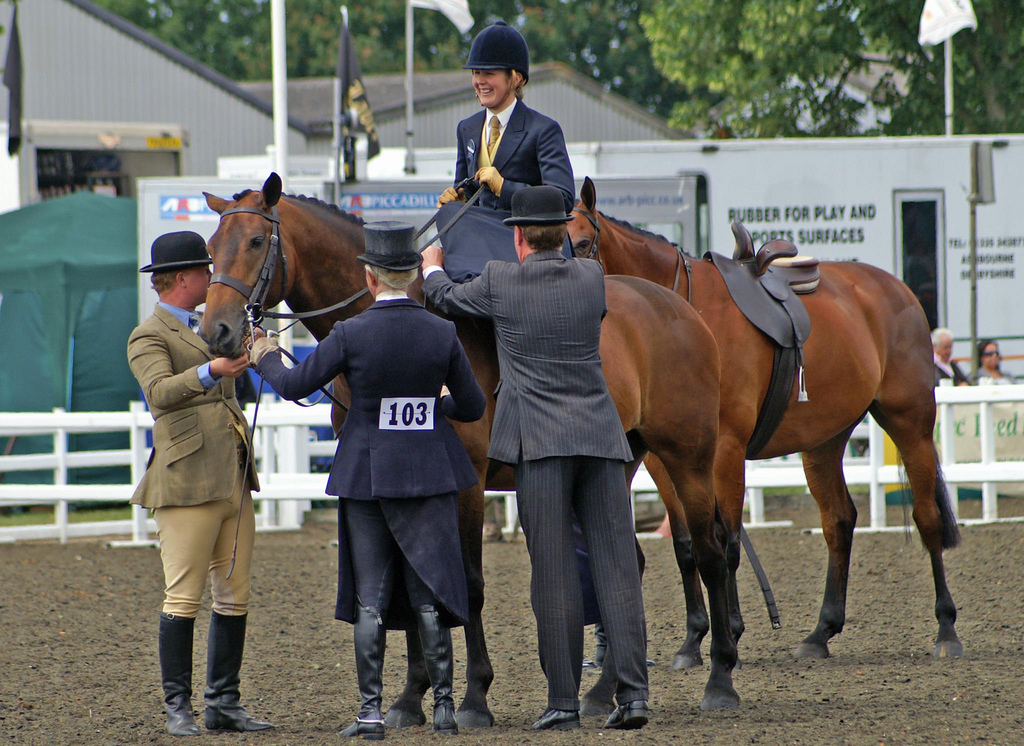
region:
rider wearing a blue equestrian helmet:
[462, 19, 535, 83]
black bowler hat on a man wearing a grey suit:
[423, 182, 648, 731]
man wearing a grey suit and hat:
[418, 181, 646, 729]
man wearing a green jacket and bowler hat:
[125, 228, 275, 735]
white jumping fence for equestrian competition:
[0, 405, 138, 548]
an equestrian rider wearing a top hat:
[253, 222, 482, 741]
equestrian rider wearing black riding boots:
[249, 215, 484, 741]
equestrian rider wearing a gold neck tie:
[449, 18, 576, 218]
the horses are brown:
[194, 171, 966, 731]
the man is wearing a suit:
[421, 181, 653, 729]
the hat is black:
[501, 183, 574, 223]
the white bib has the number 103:
[375, 395, 432, 430]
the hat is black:
[354, 220, 422, 272]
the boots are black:
[334, 604, 458, 737]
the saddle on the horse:
[566, 174, 962, 668]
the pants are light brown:
[149, 454, 252, 616]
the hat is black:
[138, 227, 215, 273]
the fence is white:
[2, 380, 1021, 551]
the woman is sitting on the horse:
[194, 15, 736, 724]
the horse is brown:
[191, 173, 748, 709]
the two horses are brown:
[194, 168, 962, 731]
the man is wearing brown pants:
[122, 228, 277, 740]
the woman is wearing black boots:
[250, 215, 486, 738]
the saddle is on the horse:
[548, 176, 961, 668]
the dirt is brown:
[1, 489, 1020, 743]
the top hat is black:
[358, 222, 423, 274]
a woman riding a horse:
[382, 2, 617, 360]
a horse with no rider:
[552, 192, 1004, 696]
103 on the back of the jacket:
[369, 395, 449, 443]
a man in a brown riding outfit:
[110, 221, 295, 743]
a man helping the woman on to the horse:
[420, 192, 709, 721]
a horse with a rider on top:
[160, 155, 772, 725]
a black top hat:
[344, 211, 422, 279]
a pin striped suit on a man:
[432, 247, 679, 713]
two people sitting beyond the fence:
[931, 313, 1023, 421]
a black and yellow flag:
[319, 10, 399, 178]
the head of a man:
[114, 215, 225, 334]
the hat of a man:
[131, 212, 204, 279]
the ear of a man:
[157, 250, 183, 290]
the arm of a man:
[134, 344, 245, 411]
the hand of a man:
[219, 353, 265, 382]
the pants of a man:
[152, 493, 280, 741]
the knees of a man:
[160, 590, 274, 630]